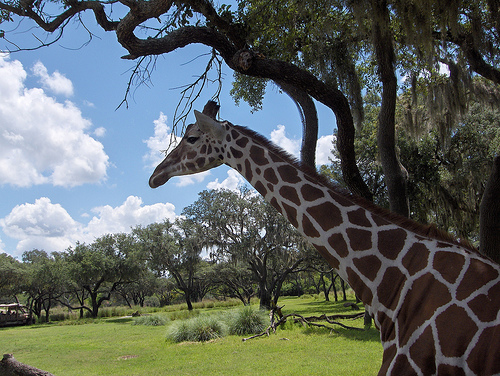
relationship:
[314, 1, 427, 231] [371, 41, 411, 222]
tree has trunk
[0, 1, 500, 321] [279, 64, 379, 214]
tree has trunk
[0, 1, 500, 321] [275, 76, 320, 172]
tree has trunk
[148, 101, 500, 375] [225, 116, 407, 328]
brown giraffe has neck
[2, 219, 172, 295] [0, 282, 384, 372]
leaves in field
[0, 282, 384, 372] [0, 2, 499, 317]
field by trees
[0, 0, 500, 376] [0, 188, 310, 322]
field by trees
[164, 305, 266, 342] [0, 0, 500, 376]
green leaves in field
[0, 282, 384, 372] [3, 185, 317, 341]
field by trees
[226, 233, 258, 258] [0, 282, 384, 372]
leaves in field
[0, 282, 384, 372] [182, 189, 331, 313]
field by tree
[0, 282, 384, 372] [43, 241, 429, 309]
field by trees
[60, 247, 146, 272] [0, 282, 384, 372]
green leaves in field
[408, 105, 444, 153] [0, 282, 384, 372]
leaves in field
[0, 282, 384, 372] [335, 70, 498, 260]
field by tree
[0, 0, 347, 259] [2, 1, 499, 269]
cloud in sky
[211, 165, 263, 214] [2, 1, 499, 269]
cloud in sky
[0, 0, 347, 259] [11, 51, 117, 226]
cloud in sky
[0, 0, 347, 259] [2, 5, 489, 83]
cloud in sky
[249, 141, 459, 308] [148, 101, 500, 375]
neck on brown giraffe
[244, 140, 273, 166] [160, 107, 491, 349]
spot on giraffe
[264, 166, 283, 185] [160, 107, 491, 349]
spot on giraffe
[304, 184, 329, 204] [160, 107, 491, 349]
spot on giraffe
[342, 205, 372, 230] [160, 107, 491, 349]
spot on giraffe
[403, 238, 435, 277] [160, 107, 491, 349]
spot on giraffe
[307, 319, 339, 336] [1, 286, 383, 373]
stick on ground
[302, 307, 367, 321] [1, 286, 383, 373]
stick on ground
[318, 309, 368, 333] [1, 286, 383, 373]
stick on ground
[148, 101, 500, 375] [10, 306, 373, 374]
brown giraffe standing in field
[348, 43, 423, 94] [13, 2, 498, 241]
sky above trees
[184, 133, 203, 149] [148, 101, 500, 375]
eye of brown giraffe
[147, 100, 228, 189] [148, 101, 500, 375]
head of brown giraffe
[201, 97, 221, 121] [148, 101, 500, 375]
ear of brown giraffe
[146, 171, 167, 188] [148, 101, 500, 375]
mouth of brown giraffe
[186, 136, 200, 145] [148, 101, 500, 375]
eye of brown giraffe